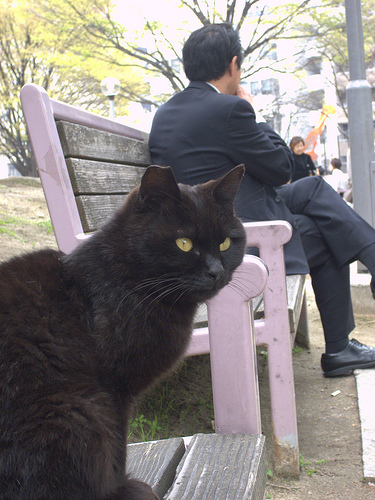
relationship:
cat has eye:
[0, 160, 246, 497] [173, 237, 196, 254]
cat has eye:
[0, 160, 246, 497] [218, 235, 233, 253]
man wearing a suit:
[150, 21, 374, 376] [149, 82, 373, 331]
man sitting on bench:
[150, 21, 374, 376] [20, 79, 309, 472]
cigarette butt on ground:
[330, 387, 344, 397] [303, 283, 375, 498]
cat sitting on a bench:
[0, 160, 246, 497] [0, 253, 267, 499]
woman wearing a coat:
[288, 131, 319, 175] [290, 153, 320, 178]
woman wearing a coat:
[328, 153, 349, 191] [326, 171, 346, 193]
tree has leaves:
[2, 1, 161, 96] [43, 38, 130, 77]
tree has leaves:
[307, 6, 374, 75] [328, 22, 343, 65]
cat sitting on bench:
[0, 160, 246, 497] [0, 253, 267, 499]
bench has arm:
[20, 79, 309, 472] [241, 222, 293, 243]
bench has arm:
[0, 253, 267, 499] [239, 257, 268, 302]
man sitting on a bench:
[150, 21, 374, 376] [20, 79, 309, 472]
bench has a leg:
[20, 79, 309, 472] [268, 335, 299, 481]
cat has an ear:
[0, 160, 246, 497] [138, 164, 179, 203]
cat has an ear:
[0, 160, 246, 497] [216, 164, 247, 203]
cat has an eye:
[0, 160, 246, 497] [173, 237, 196, 254]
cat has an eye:
[0, 160, 246, 497] [218, 235, 233, 253]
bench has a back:
[20, 79, 309, 472] [18, 89, 156, 227]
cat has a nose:
[0, 160, 246, 497] [209, 266, 228, 281]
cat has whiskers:
[0, 160, 246, 497] [114, 275, 276, 316]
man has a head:
[150, 21, 374, 376] [180, 26, 247, 93]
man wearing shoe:
[150, 21, 374, 376] [322, 341, 374, 375]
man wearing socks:
[150, 21, 374, 376] [326, 345, 346, 353]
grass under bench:
[136, 407, 173, 435] [20, 79, 309, 472]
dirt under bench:
[185, 367, 206, 427] [20, 79, 309, 472]